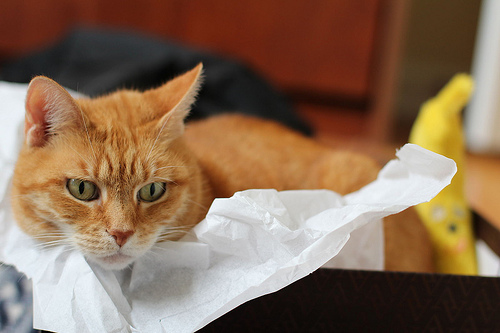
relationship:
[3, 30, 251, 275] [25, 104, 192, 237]
cat has head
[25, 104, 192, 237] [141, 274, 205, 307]
head has shadow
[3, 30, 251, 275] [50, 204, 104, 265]
cat has cheek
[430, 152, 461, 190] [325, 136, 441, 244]
edge of paper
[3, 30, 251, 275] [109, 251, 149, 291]
cat has chin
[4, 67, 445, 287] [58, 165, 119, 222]
cat has eye